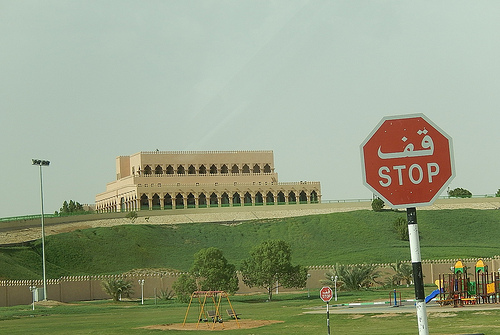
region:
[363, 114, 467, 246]
stop sign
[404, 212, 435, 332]
black and white pole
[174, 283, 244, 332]
swing set with yellow metal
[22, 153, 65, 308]
light with metal post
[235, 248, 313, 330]
tree with green leaves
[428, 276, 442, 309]
blue slide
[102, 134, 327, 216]
tan building with multiple windows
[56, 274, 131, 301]
tan fence and green shrub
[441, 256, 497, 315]
yellow, green, and red play area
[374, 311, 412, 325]
dirt and grass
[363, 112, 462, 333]
white and red stop sign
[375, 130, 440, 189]
white letters on red sign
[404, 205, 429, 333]
white and black sign pole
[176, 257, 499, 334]
playground equipment behind sign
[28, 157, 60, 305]
tall light post on grass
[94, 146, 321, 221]
two story building with archway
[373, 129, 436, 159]
markings on stopsign in different language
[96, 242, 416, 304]
green trees by fence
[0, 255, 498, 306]
wooden fence behind trees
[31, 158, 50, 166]
lights on top of pole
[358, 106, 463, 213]
stop sign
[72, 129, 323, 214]
tan building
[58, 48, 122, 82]
white clouds in blue sky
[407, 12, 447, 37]
white clouds in blue sky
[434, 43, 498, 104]
white clouds in blue sky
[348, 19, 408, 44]
white clouds in blue sky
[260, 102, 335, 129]
white clouds in blue sky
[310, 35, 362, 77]
white clouds in blue sky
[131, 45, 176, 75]
white clouds in blue sky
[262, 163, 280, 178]
window of a building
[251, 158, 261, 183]
window of a building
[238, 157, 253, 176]
window of a building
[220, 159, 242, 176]
window of a building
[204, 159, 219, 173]
window of a building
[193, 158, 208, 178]
window of a building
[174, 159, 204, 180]
window of a building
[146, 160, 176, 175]
window of a building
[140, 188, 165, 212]
window of a building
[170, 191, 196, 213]
window of a building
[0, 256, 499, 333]
park area for children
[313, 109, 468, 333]
stop signs for traffic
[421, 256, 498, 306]
colorful jungle gym on playground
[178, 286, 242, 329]
swing set in patch of dirt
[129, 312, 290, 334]
dirt patch for cushioning falls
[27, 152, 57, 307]
tall light fixture for playground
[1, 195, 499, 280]
landscape between building and playground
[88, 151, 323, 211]
large building on top of hill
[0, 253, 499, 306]
tall fence enclosing playground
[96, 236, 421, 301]
trees and shrubs on playground